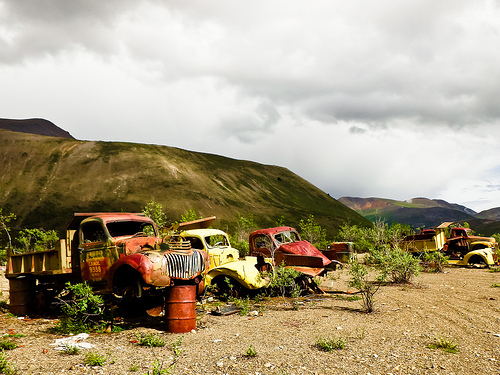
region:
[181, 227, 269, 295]
Old Dilapidated Yellow Vehicle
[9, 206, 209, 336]
A Red Dilapidated Truck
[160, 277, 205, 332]
A Rusted Metal Oil Drum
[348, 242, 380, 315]
A Green desert Shrub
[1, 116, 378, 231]
A Massive Hill in the Background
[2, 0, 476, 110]
A Grey Cloudy Sky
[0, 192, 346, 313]
A Group of Three Broken Down Vehicles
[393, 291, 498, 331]
Slightly Disturbed Rocky Ground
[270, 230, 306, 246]
Old Broken Glass Windsheild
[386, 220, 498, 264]
Two Broken Vehicles in the background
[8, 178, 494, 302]
a junkyard of old vehicles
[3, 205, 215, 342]
an old truck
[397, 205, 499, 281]
a broken old truck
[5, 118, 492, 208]
a mountain view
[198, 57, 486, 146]
a cloudy sky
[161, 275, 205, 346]
an old thin tall pail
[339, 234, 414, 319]
a bunch of bushes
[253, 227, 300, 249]
a broken glass window of a car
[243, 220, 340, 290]
a red old broken car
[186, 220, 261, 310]
a yellow old broken car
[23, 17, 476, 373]
several old trucks on dirt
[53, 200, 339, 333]
several old broken trucks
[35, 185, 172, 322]
un-kept old truck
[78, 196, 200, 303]
front of old broken truck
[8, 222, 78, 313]
back of old truck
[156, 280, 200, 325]
orange barrel on dirt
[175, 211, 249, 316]
front of yellow truck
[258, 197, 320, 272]
front of red truck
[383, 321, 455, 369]
bushes on the dirt ground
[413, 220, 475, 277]
more trucks in background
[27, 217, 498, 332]
a lot of abandoned trucks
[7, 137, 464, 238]
green big mountains in the back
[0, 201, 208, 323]
abandoned red truck in the left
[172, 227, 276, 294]
abandoned big yellow truck between two red cars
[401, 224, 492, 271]
part of a yellow abandoned truck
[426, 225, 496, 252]
part of a red truck in the bottom nexto to a yellow chasis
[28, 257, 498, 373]
brown ground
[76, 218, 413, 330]
some bushes between cars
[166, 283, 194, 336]
red garbage can in front of a red truck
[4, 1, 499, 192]
cloudy and grey sky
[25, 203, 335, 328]
old trucks parked in dirt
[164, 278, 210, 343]
red oil drum in dirt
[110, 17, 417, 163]
grey clouds in sky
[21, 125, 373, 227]
large dirt mound in the background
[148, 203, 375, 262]
bushes growing through trucks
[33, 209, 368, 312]
old pick up trucks rusting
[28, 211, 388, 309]
line of red and yellow trucks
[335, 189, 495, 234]
mountains in the background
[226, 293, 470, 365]
gravel road in front of trucks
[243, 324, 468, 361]
grass growing on road